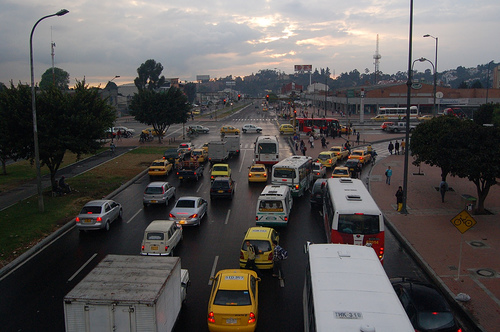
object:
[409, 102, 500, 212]
trees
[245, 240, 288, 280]
men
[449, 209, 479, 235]
sign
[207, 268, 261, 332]
taxi cab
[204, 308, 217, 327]
brake light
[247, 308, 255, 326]
brake light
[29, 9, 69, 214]
street light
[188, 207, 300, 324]
cab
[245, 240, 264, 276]
men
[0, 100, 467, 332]
road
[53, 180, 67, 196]
people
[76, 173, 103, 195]
grass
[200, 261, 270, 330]
cab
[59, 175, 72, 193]
person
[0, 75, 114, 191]
tree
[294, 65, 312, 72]
sign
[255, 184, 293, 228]
vehicle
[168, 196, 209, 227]
vehicle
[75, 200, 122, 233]
vehicle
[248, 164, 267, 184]
vehicle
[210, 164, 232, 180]
vehicle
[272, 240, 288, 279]
person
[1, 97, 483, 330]
street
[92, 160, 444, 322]
cars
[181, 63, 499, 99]
hills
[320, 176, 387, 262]
bus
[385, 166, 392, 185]
person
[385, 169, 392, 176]
shirt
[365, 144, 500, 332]
sidewalk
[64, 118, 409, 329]
traffic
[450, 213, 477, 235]
bike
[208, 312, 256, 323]
lights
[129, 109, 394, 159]
intersection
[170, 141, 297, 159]
crosswalk